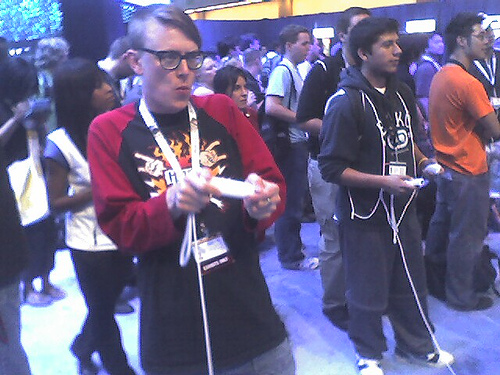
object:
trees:
[0, 0, 61, 35]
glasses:
[138, 47, 204, 69]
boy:
[86, 4, 285, 375]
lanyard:
[139, 98, 201, 178]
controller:
[209, 177, 255, 198]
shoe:
[357, 356, 385, 375]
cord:
[191, 214, 215, 374]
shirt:
[426, 63, 493, 175]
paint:
[184, 0, 294, 20]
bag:
[256, 100, 277, 142]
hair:
[55, 62, 97, 159]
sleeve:
[85, 102, 179, 253]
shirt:
[86, 93, 292, 375]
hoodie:
[317, 65, 415, 228]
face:
[155, 43, 199, 107]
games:
[404, 178, 424, 188]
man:
[318, 15, 446, 371]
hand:
[382, 174, 411, 196]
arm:
[207, 92, 286, 226]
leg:
[341, 221, 389, 361]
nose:
[393, 43, 403, 55]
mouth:
[390, 58, 400, 61]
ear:
[358, 48, 368, 60]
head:
[349, 18, 402, 73]